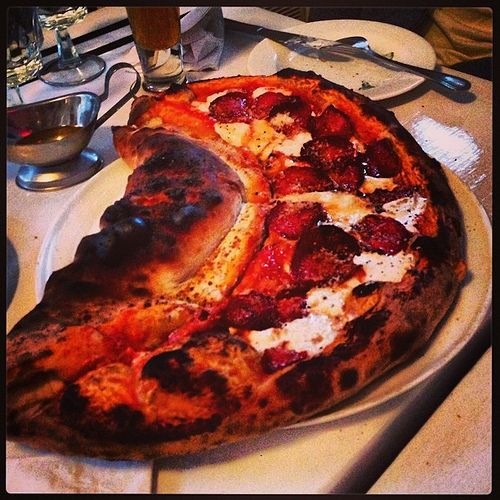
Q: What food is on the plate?
A: Pizza.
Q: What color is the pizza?
A: Red.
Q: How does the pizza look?
A: Burnt.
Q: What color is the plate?
A: White.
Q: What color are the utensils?
A: Silver.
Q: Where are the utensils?
A: On the plate.